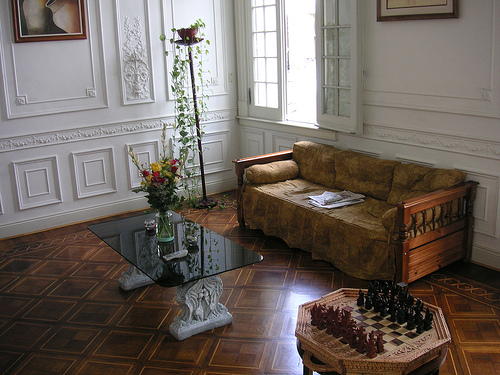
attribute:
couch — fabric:
[232, 140, 472, 287]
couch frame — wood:
[231, 150, 481, 287]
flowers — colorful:
[112, 124, 230, 326]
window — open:
[234, 1, 333, 132]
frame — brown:
[16, 11, 97, 39]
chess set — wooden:
[294, 282, 451, 371]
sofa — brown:
[209, 102, 473, 283]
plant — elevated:
[172, 11, 224, 218]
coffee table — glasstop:
[101, 203, 266, 360]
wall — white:
[0, 2, 240, 219]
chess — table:
[284, 276, 461, 372]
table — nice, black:
[70, 180, 295, 351]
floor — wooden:
[2, 189, 497, 372]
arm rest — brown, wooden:
[230, 137, 277, 170]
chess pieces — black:
[302, 299, 394, 357]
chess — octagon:
[285, 267, 460, 363]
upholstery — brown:
[244, 141, 466, 283]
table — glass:
[106, 198, 278, 321]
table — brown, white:
[292, 280, 445, 373]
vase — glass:
[156, 205, 176, 241]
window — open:
[278, 4, 316, 121]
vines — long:
[158, 11, 213, 211]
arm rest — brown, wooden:
[377, 190, 497, 256]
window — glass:
[242, 0, 341, 140]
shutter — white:
[234, 1, 291, 127]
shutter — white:
[314, 0, 367, 137]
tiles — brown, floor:
[6, 254, 119, 374]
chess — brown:
[309, 300, 319, 324]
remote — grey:
[160, 246, 188, 264]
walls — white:
[31, 81, 150, 176]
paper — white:
[303, 186, 368, 212]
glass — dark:
[94, 211, 256, 291]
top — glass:
[83, 209, 264, 289]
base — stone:
[117, 263, 233, 341]